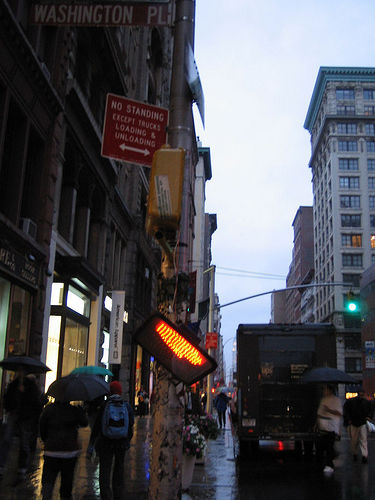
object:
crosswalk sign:
[134, 311, 218, 386]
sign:
[100, 92, 170, 168]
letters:
[110, 99, 117, 107]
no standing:
[111, 99, 165, 122]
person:
[40, 396, 89, 498]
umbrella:
[0, 352, 52, 370]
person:
[82, 396, 107, 461]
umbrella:
[45, 365, 111, 406]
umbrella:
[301, 359, 362, 384]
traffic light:
[345, 299, 360, 318]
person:
[85, 379, 135, 500]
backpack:
[100, 398, 131, 440]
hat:
[108, 378, 123, 394]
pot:
[182, 450, 197, 489]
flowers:
[182, 424, 206, 456]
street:
[208, 388, 374, 499]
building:
[303, 65, 374, 437]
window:
[338, 157, 349, 171]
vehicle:
[233, 322, 337, 462]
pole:
[150, 0, 196, 500]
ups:
[259, 364, 273, 376]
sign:
[31, 0, 178, 26]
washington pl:
[34, 4, 163, 23]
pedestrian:
[314, 380, 343, 478]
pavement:
[3, 417, 375, 499]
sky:
[195, 0, 372, 322]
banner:
[108, 288, 126, 366]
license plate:
[240, 417, 257, 427]